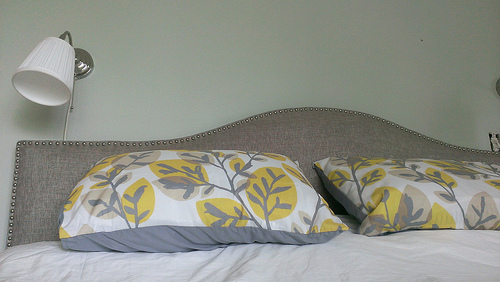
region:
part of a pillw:
[198, 206, 236, 244]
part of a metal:
[51, 111, 67, 136]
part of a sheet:
[381, 223, 397, 249]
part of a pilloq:
[208, 171, 236, 210]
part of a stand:
[57, 91, 77, 130]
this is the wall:
[136, 38, 374, 86]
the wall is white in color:
[295, 2, 408, 66]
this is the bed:
[282, 113, 344, 142]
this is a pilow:
[66, 153, 200, 205]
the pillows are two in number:
[141, 164, 432, 229]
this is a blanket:
[318, 240, 474, 278]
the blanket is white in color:
[371, 253, 451, 279]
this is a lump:
[19, 35, 83, 105]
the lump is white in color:
[33, 40, 66, 77]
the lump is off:
[11, 58, 58, 95]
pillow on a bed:
[45, 140, 356, 264]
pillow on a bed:
[306, 135, 498, 237]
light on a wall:
[7, 27, 106, 118]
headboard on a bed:
[0, 102, 498, 245]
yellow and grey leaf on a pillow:
[244, 162, 294, 224]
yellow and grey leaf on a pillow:
[194, 193, 254, 230]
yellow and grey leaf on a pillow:
[117, 175, 157, 226]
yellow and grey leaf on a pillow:
[62, 180, 84, 212]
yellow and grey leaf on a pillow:
[360, 165, 385, 192]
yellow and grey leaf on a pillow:
[327, 165, 354, 190]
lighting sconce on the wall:
[12, 18, 97, 116]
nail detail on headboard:
[5, 115, 499, 237]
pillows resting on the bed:
[64, 143, 492, 253]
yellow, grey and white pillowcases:
[103, 154, 328, 241]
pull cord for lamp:
[67, 66, 79, 116]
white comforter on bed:
[315, 242, 499, 279]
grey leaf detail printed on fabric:
[246, 163, 293, 223]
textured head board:
[30, 157, 52, 229]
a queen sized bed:
[4, 80, 497, 279]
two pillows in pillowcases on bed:
[80, 144, 499, 261]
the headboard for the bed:
[11, 103, 498, 233]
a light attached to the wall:
[13, 31, 93, 106]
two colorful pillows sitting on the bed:
[53, 146, 498, 251]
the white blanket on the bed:
[1, 234, 497, 277]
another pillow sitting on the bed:
[318, 138, 498, 232]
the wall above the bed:
[2, 1, 499, 141]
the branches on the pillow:
[172, 153, 321, 218]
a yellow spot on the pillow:
[243, 166, 298, 219]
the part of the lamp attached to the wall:
[68, 47, 93, 78]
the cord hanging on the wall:
[58, 103, 77, 143]